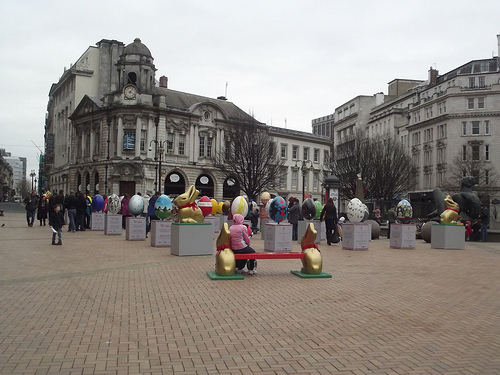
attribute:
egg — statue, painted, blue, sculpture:
[152, 194, 175, 222]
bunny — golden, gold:
[172, 187, 209, 225]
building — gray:
[72, 37, 335, 203]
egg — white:
[127, 193, 146, 217]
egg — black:
[298, 196, 322, 222]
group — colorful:
[92, 192, 482, 258]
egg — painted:
[88, 189, 106, 235]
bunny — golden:
[301, 225, 328, 275]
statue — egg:
[389, 199, 417, 250]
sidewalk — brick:
[3, 253, 499, 374]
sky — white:
[3, 2, 499, 76]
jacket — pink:
[229, 215, 249, 249]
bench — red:
[206, 247, 334, 280]